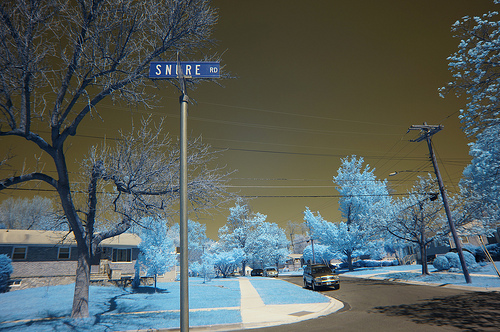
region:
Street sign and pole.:
[149, 52, 239, 330]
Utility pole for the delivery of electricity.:
[401, 117, 481, 288]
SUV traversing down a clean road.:
[300, 257, 350, 296]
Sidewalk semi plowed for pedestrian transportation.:
[230, 265, 271, 329]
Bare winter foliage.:
[3, 5, 203, 322]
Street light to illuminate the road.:
[377, 162, 438, 190]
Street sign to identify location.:
[139, 46, 230, 98]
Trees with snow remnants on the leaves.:
[311, 150, 395, 274]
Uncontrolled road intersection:
[330, 219, 497, 328]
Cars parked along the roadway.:
[248, 259, 288, 286]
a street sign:
[127, 28, 297, 257]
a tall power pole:
[370, 92, 480, 304]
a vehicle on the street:
[280, 233, 385, 325]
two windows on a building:
[15, 238, 80, 274]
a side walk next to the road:
[224, 260, 282, 330]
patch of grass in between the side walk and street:
[234, 267, 330, 315]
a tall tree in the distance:
[310, 134, 442, 274]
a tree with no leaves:
[20, 24, 252, 303]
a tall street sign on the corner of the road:
[127, 35, 296, 330]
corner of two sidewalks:
[207, 269, 279, 331]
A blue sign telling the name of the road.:
[147, 57, 219, 77]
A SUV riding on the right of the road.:
[302, 261, 339, 291]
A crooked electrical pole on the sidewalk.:
[402, 120, 476, 284]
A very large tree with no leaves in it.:
[2, 2, 235, 321]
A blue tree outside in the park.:
[131, 210, 178, 290]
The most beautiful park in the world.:
[0, 0, 496, 326]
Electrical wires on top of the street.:
[0, 57, 497, 199]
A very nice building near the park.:
[0, 227, 180, 289]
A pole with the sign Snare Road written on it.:
[151, 48, 225, 329]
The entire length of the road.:
[232, 274, 497, 328]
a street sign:
[122, 26, 245, 106]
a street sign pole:
[139, 49, 288, 327]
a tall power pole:
[388, 88, 489, 309]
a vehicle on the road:
[280, 255, 360, 315]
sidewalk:
[227, 269, 264, 331]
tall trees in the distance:
[320, 140, 410, 266]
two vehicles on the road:
[236, 253, 282, 288]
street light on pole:
[365, 157, 460, 185]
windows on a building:
[6, 232, 86, 269]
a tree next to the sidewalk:
[1, 15, 148, 312]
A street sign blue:
[149, 53, 221, 77]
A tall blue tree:
[261, 128, 411, 268]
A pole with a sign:
[146, 50, 232, 330]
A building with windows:
[3, 213, 154, 295]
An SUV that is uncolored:
[291, 258, 353, 292]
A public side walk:
[217, 261, 257, 329]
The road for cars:
[333, 278, 399, 327]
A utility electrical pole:
[408, 104, 487, 297]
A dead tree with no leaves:
[11, 41, 142, 291]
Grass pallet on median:
[258, 276, 295, 301]